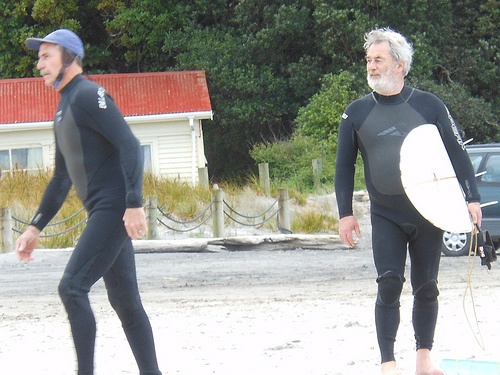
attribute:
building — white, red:
[0, 68, 215, 204]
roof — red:
[0, 62, 214, 125]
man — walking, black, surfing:
[13, 31, 161, 373]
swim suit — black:
[29, 72, 165, 371]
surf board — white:
[398, 121, 488, 236]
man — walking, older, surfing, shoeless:
[335, 24, 486, 373]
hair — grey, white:
[360, 25, 414, 93]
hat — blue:
[22, 27, 88, 88]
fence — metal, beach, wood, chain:
[1, 184, 295, 252]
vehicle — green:
[438, 142, 500, 259]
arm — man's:
[434, 90, 478, 208]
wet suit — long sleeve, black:
[28, 71, 163, 373]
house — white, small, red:
[1, 65, 212, 228]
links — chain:
[154, 199, 214, 237]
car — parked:
[435, 139, 500, 257]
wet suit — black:
[333, 84, 483, 362]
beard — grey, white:
[364, 68, 397, 96]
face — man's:
[363, 43, 405, 92]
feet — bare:
[379, 348, 451, 373]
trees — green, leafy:
[3, 2, 500, 192]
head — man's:
[35, 28, 89, 89]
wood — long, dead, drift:
[134, 223, 362, 254]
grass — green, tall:
[0, 175, 344, 254]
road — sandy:
[3, 232, 500, 370]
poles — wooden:
[2, 156, 329, 253]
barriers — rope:
[13, 183, 280, 252]